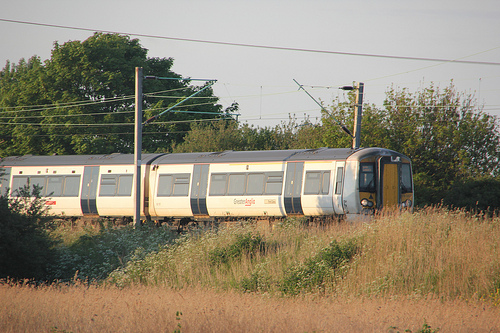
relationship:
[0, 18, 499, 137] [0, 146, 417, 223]
power lines crossing over a train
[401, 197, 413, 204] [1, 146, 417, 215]
lights on train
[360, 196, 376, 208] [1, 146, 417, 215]
lights on train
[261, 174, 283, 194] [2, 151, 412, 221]
window on train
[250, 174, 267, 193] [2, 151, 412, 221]
window on train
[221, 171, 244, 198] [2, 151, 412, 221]
window on train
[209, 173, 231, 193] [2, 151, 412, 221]
window on train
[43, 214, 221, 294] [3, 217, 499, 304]
flowers on side of hill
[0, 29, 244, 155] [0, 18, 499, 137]
trees behind power lines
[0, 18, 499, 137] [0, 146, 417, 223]
power lines above train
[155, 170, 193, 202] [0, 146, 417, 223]
window on side of train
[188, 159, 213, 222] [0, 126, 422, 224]
door of train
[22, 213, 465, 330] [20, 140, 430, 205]
weeds in front of train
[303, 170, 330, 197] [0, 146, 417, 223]
window of train